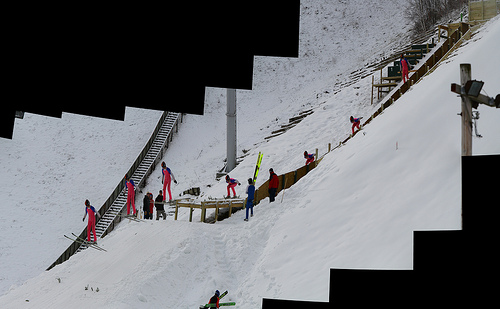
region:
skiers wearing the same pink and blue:
[49, 42, 430, 287]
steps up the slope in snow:
[263, 97, 316, 158]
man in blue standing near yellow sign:
[233, 145, 265, 232]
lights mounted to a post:
[442, 52, 493, 160]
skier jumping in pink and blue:
[61, 185, 116, 265]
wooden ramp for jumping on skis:
[165, 160, 327, 255]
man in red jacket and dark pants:
[262, 159, 291, 214]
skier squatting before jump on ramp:
[293, 145, 323, 182]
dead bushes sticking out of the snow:
[395, 0, 452, 50]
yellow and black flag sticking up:
[250, 147, 265, 191]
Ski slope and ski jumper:
[19, 12, 489, 292]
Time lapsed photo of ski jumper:
[41, 49, 424, 262]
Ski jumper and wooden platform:
[182, 169, 249, 224]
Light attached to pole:
[454, 50, 488, 104]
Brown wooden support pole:
[448, 53, 483, 158]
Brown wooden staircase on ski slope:
[43, 104, 199, 270]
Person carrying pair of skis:
[201, 289, 239, 307]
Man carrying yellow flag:
[239, 143, 264, 223]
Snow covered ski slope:
[32, 123, 322, 307]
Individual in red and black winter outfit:
[264, 163, 284, 201]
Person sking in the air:
[80, 196, 98, 243]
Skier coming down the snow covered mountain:
[347, 115, 363, 135]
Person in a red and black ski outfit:
[122, 173, 137, 216]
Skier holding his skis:
[240, 150, 263, 220]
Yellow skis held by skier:
[250, 148, 261, 178]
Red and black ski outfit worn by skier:
[393, 53, 414, 83]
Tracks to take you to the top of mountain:
[42, 108, 182, 268]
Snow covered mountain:
[1, 0, 497, 306]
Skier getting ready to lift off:
[221, 171, 239, 196]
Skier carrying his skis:
[198, 289, 235, 308]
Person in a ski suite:
[73, 186, 111, 253]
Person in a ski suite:
[115, 169, 142, 229]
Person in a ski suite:
[155, 159, 184, 212]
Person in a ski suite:
[138, 180, 170, 222]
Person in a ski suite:
[208, 153, 240, 212]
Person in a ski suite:
[195, 284, 225, 302]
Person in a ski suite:
[263, 164, 293, 212]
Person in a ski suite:
[295, 149, 322, 178]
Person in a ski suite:
[335, 102, 369, 153]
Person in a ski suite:
[382, 53, 414, 92]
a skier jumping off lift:
[20, 103, 321, 255]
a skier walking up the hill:
[176, 269, 236, 306]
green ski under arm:
[191, 286, 253, 306]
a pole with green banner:
[236, 133, 275, 191]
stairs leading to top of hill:
[127, 32, 377, 207]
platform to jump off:
[162, 193, 251, 232]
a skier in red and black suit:
[72, 185, 109, 260]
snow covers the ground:
[11, 1, 468, 306]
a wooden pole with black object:
[438, 50, 493, 157]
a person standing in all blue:
[229, 167, 269, 224]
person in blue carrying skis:
[237, 142, 269, 221]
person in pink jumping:
[59, 192, 109, 257]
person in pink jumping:
[118, 170, 144, 226]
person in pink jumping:
[151, 155, 185, 212]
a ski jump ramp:
[164, 5, 489, 225]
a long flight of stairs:
[33, 108, 210, 274]